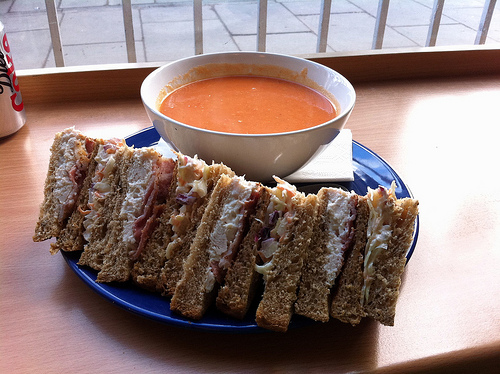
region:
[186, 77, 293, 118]
tomato soup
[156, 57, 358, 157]
tomato soup in whjite bowl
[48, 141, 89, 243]
tuna salad sandwich on wheat bread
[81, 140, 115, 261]
tuna salad sandwich on wheat bread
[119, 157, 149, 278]
tuna salad sandwich on wheat bread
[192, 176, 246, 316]
tuna salad sandwich on wheat bread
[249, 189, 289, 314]
tuna salad sandwich on wheat bread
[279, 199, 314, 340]
tuna salad sandwich on wheat bread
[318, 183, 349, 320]
tuna salad sandwich on wheat bread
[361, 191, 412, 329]
tuna salad sandwich on wheat bread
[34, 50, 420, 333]
Sandwiches and Tomato soup.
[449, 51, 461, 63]
part of a table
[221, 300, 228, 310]
edge of a plate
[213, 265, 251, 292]
part of a bread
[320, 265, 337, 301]
edge of a bread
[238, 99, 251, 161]
edge of a bowl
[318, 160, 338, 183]
part of a tissue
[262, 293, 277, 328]
edge of a bread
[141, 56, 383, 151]
a bowl of tomato soup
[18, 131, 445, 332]
a large turkey sandwich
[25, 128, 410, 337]
a big sandwich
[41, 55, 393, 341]
lunch on a blue plate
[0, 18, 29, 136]
A can of Diet Coke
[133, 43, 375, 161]
tomato soup in a bowl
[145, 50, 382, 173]
a white bowl filled with soup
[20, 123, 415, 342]
a sandwich made with wheat bread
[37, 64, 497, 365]
a meal on a counter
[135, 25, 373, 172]
bowl of soup on a napkin and plate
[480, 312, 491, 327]
top of a table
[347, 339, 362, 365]
side of a table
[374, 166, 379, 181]
part of a plate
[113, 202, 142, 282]
part of a bread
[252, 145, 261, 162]
part of a bowl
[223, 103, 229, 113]
part of the soup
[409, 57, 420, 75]
part of a window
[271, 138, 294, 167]
side of a bowl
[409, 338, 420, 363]
edge of a table